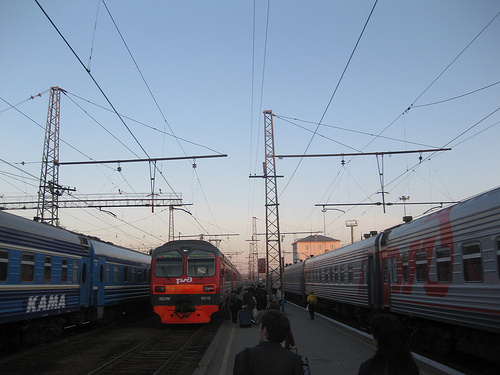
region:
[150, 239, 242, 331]
A red train on train tracks.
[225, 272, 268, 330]
A group of people waiting to board on a train.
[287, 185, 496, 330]
A gray train with red markings.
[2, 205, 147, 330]
A blue train with "KAMA" written on the side.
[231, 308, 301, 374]
A man looking at a train.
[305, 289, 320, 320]
A person wearing a yellow shirt.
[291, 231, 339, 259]
A building in the background of the stopped trains.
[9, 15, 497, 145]
A blue sky above the trains.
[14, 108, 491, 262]
A sunset above the trains.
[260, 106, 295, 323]
A metal tower in the walkway.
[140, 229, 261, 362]
red light rail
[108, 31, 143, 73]
white clouds in blue sky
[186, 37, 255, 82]
white clouds in blue sky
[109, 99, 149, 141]
white clouds in blue sky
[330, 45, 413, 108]
white clouds in blue sky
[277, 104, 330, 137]
white clouds in blue sky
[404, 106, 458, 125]
white clouds in blue sky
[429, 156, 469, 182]
white clouds in blue sky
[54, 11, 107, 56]
white clouds in blue sky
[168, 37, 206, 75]
white clouds in blue sky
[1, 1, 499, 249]
electric lines over the train tracks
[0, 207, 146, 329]
bluer train for passengers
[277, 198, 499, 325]
silver passenger car with red letters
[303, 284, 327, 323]
potential passenger in a yellow shirt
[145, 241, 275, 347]
a train is boarding passengers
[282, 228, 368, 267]
sun shines off a building near the station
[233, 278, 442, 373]
walkway between tracks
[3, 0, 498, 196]
a clear blue sky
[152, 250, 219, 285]
a windshield in two parts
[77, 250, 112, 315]
doors for entry and exit of train cars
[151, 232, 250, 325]
train in the railway station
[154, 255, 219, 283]
front glass with wipers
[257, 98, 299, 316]
electric pole with cables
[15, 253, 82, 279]
windows of the train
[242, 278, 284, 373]
people standing and walking in the platform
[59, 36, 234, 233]
lot of electric cables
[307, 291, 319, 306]
a person wearing yellow color t-shirt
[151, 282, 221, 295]
headlight of the train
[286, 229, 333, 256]
building behind the railway station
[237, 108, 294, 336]
electric pole with some people standing in the platform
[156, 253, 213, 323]
the head of a train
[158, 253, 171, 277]
a window of a train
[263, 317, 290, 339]
The head of a man on the left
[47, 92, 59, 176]
Electric rail on the left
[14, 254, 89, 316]
A blue compartment of a train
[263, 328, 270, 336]
An ear of a man on the right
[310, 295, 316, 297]
A yellow t-shirt of a man on the right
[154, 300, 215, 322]
The engine of a train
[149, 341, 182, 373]
Railwayline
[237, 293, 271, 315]
A crowd of people